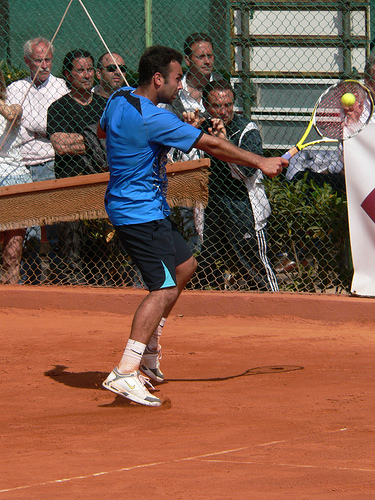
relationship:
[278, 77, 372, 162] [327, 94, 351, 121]
racket has strings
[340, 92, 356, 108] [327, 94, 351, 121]
ball on strings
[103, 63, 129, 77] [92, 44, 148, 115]
sunglasses on man's head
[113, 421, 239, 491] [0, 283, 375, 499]
clay in court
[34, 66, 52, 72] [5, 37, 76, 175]
man with mustache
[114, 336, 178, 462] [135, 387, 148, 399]
shoes are white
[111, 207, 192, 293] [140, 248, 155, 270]
shorts are black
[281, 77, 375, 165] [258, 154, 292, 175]
racket in hand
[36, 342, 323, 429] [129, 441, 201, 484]
shadow on ground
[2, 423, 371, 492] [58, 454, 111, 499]
white line in dirt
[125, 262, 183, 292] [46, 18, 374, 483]
shorts on man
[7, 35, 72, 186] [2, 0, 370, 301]
man behind fence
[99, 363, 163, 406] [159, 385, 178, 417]
foot kicking up dirt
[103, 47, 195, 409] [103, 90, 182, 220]
man wearing blue shirt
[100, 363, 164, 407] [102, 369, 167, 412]
foot are in shoe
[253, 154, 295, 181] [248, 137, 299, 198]
hand gripping handle